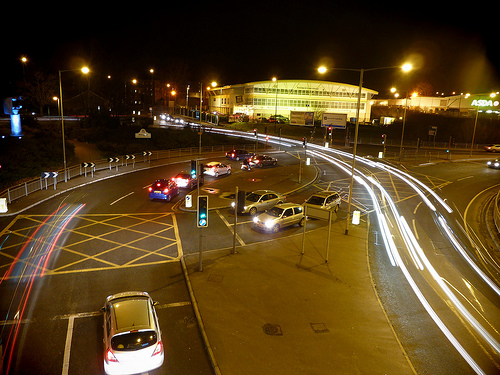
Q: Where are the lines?
A: In intersection.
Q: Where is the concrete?
A: Middle intersection.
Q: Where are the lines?
A: On road.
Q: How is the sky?
A: Black.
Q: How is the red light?
A: On.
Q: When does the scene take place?
A: Night.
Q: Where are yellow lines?
A: On the street.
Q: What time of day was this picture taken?
A: At night.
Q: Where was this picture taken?
A: At an intersection.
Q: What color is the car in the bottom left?
A: White.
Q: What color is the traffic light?
A: Green.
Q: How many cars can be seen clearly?
A: Nine.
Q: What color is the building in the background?
A: White.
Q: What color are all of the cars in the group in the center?
A: Silver.